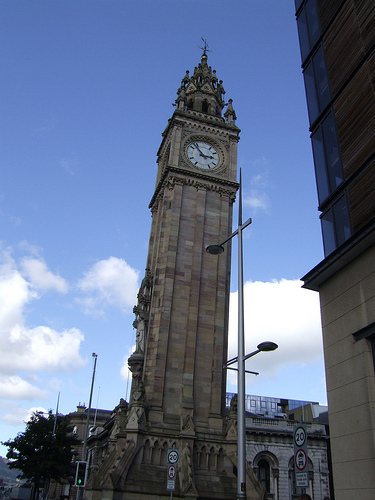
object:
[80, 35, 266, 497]
clock tower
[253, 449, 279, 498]
window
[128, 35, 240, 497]
clock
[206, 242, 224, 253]
light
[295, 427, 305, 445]
20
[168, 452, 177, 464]
20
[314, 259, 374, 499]
wall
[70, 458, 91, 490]
traffic light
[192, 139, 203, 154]
hand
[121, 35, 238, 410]
tower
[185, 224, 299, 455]
streetlight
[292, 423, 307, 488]
sign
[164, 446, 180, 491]
sign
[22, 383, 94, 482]
distance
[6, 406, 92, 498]
tree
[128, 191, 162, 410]
wall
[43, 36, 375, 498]
building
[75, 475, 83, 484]
green light